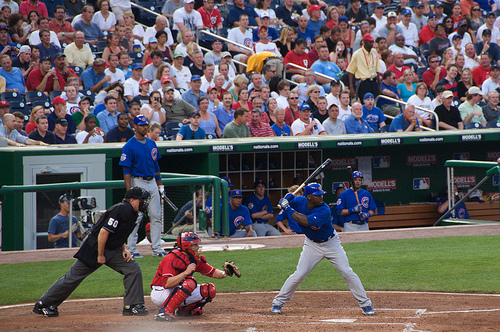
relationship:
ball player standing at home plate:
[268, 183, 379, 315] [321, 314, 354, 329]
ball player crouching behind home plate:
[148, 230, 241, 322] [314, 306, 361, 326]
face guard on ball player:
[136, 188, 156, 216] [29, 184, 151, 319]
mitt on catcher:
[221, 259, 241, 278] [150, 230, 233, 321]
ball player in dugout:
[335, 170, 377, 233] [126, 147, 497, 231]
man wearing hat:
[346, 33, 382, 108] [360, 33, 376, 42]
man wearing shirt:
[346, 33, 382, 108] [345, 45, 382, 81]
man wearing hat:
[359, 87, 386, 130] [362, 87, 376, 99]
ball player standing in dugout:
[118, 114, 169, 260] [19, 162, 246, 262]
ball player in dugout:
[268, 183, 379, 315] [166, 140, 497, 241]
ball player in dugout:
[148, 230, 241, 322] [166, 140, 497, 241]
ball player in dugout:
[118, 114, 169, 260] [166, 140, 497, 241]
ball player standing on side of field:
[271, 183, 383, 314] [1, 230, 498, 330]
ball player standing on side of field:
[144, 227, 242, 322] [1, 230, 498, 330]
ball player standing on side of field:
[37, 184, 149, 319] [1, 230, 498, 330]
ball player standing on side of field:
[117, 114, 169, 255] [1, 230, 498, 330]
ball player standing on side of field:
[332, 167, 374, 226] [1, 230, 498, 330]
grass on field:
[0, 233, 500, 311] [5, 218, 494, 329]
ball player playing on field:
[268, 183, 379, 315] [1, 230, 498, 330]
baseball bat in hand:
[273, 150, 331, 213] [278, 195, 292, 213]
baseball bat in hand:
[273, 150, 331, 213] [284, 189, 295, 199]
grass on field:
[7, 221, 494, 329] [5, 260, 499, 327]